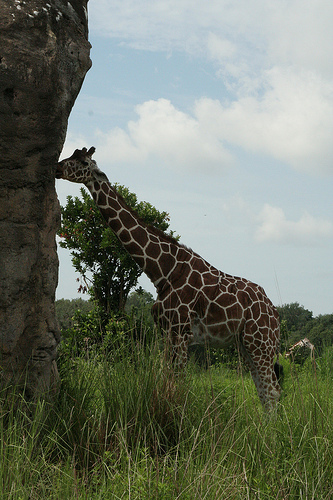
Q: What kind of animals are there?
A: Giraffes.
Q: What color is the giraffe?
A: Brown.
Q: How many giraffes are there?
A: One.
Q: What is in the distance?
A: Trees.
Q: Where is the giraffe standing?
A: Grass.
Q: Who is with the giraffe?
A: No one.